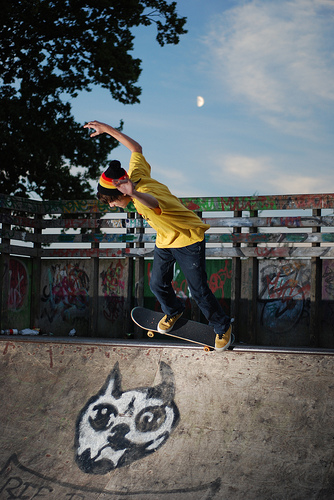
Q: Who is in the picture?
A: A boy.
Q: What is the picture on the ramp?
A: Black and white painted dog.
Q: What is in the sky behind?
A: A half moon and some clouds.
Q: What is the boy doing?
A: Skateboarding on a ramp.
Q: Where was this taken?
A: Skate park.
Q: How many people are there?
A: 1.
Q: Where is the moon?
A: In the sky.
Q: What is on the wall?
A: Graffiti.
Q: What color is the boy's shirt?
A: Yellow.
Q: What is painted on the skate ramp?
A: Dog.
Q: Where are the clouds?
A: In the sky.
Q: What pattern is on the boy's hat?
A: Stripes.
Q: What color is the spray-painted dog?
A: Black and white.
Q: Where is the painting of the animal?
A: On the ramp.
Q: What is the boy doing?
A: Riding a skateboard.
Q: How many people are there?
A: 1.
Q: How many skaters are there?
A: 1.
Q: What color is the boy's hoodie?
A: Yellow.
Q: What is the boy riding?
A: Skateboard.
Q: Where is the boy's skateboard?
A: Under him.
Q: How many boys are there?
A: One.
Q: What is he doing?
A: Skating.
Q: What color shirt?
A: Yellow.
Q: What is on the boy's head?
A: Cap.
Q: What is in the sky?
A: Moon and clouds.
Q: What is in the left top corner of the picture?
A: Tree.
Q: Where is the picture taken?
A: At a skateboarding rink.